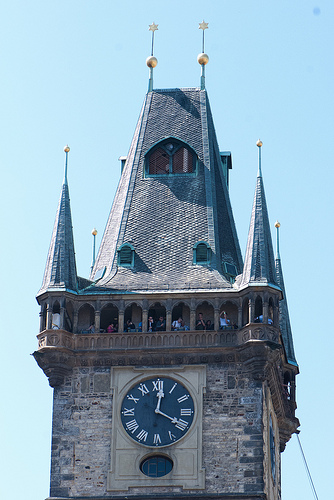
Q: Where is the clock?
A: On the tower.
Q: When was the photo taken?
A: Day time.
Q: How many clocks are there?
A: One.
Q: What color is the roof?
A: Gray and green.